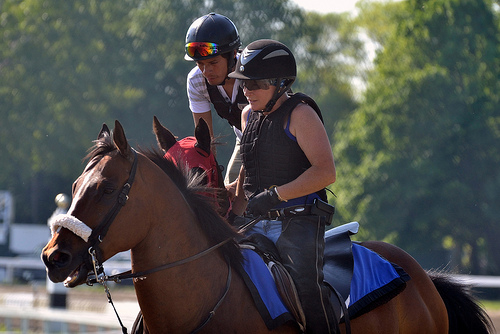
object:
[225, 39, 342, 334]
woman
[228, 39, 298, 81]
helmet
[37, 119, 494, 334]
horse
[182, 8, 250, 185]
man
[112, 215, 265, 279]
strap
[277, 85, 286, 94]
ear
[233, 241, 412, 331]
blanket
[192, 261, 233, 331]
leather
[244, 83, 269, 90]
shades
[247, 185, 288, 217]
gloves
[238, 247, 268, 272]
saddle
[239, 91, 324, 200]
vest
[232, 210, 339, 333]
pants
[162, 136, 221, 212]
mask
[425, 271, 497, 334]
tail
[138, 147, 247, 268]
mane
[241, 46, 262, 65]
logo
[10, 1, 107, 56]
leaves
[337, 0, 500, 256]
trees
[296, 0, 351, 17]
sky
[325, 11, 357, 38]
branches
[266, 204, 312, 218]
belt